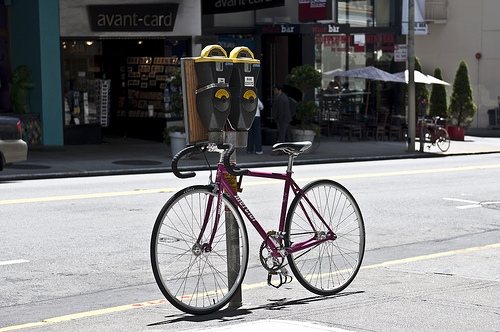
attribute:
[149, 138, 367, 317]
bike — red, purple, pink, parked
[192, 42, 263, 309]
parking meter — yellow, black, double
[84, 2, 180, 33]
sign — black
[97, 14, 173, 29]
lettering — white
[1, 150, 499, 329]
street — pubic, paved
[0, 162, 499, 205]
line — yellow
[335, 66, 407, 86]
umbrella — large, white, covering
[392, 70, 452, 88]
umbrella — white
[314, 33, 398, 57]
lettering — red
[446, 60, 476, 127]
tree — trimmed, green, potted, large, pine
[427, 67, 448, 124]
tree — potted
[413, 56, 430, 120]
tree — potted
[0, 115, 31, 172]
vehicle — motorized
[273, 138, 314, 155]
seat — black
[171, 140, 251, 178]
handle bars — black, curved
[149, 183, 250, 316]
wheel — spoked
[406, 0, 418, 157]
pole — large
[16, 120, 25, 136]
tail light — red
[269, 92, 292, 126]
suit — blue